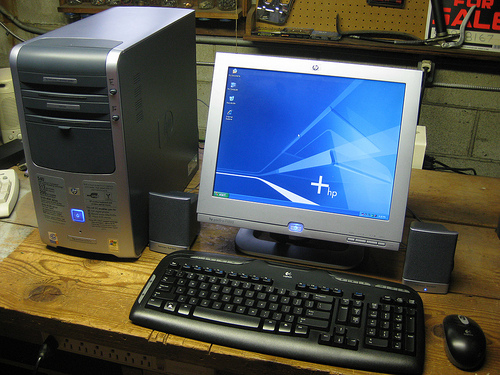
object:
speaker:
[144, 184, 205, 254]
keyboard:
[125, 245, 427, 373]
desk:
[1, 148, 495, 369]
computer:
[172, 40, 426, 269]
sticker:
[47, 230, 58, 247]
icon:
[223, 109, 235, 122]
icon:
[225, 94, 237, 107]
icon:
[229, 68, 241, 78]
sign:
[426, 1, 498, 52]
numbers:
[484, 32, 496, 44]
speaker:
[393, 220, 470, 305]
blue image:
[212, 65, 407, 220]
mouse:
[439, 309, 494, 375]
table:
[6, 217, 124, 353]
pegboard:
[253, 2, 426, 40]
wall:
[3, 39, 498, 179]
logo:
[67, 207, 87, 226]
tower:
[3, 1, 203, 268]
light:
[71, 209, 83, 224]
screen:
[194, 49, 424, 254]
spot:
[449, 336, 468, 350]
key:
[186, 287, 197, 297]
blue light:
[419, 287, 433, 295]